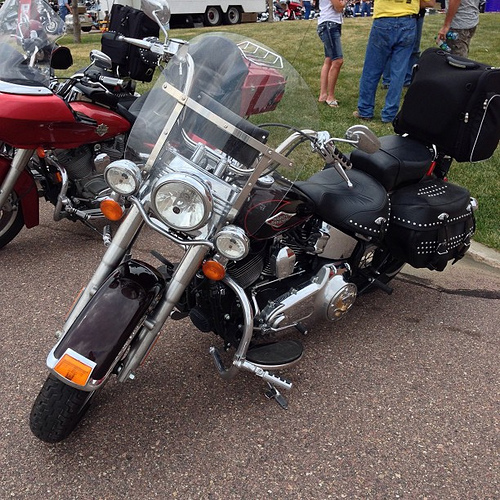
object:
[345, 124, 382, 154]
mirror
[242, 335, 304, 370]
kickstand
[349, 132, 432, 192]
rider seat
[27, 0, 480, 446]
motorcycle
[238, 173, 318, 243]
gas tank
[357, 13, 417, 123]
jeans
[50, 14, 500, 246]
grass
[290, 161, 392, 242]
seat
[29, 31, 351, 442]
steering assembly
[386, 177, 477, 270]
bag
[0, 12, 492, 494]
ground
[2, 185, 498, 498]
asphaly\t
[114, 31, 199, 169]
bars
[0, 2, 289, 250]
motorcyle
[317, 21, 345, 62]
shorts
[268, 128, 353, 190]
handlebar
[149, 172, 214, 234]
headlight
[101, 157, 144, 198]
headlights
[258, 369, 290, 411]
kickstand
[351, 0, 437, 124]
man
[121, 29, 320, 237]
windshield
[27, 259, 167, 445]
tire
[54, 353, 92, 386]
reflector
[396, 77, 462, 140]
backrest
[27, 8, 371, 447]
front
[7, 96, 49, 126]
red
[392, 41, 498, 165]
suitecase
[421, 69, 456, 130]
black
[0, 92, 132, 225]
frame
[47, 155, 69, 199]
chrome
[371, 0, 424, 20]
shirt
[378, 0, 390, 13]
yellow